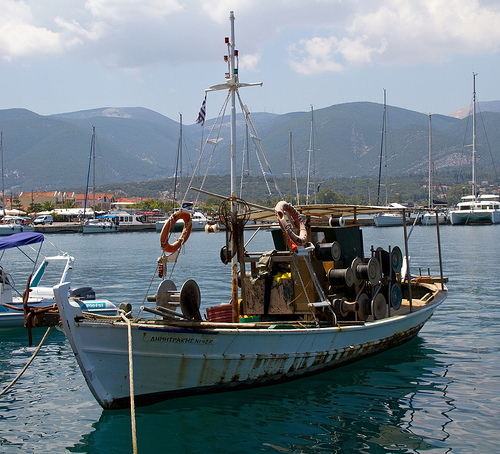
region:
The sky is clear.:
[267, 28, 444, 86]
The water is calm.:
[370, 376, 480, 438]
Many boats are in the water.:
[26, 83, 497, 427]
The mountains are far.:
[27, 82, 468, 193]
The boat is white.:
[52, 291, 442, 401]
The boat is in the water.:
[35, 189, 469, 427]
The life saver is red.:
[149, 208, 207, 259]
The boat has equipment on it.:
[95, 55, 433, 432]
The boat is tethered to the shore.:
[53, 12, 468, 424]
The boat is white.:
[445, 186, 499, 234]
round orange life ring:
[271, 191, 311, 253]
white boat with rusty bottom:
[52, 302, 449, 409]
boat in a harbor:
[59, 185, 454, 432]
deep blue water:
[327, 371, 478, 444]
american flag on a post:
[192, 82, 213, 169]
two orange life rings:
[152, 193, 317, 259]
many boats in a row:
[297, 97, 498, 227]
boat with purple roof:
[1, 227, 61, 342]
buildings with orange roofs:
[15, 185, 150, 218]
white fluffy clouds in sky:
[304, 9, 489, 64]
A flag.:
[174, 83, 224, 141]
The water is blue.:
[458, 232, 499, 380]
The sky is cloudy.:
[28, 7, 183, 94]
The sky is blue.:
[29, 12, 168, 95]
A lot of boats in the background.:
[1, 192, 151, 237]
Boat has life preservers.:
[137, 180, 317, 263]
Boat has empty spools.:
[315, 242, 416, 331]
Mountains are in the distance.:
[299, 81, 493, 186]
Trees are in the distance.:
[320, 160, 421, 196]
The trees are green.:
[313, 162, 381, 191]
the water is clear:
[337, 368, 423, 449]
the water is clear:
[313, 401, 386, 448]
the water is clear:
[342, 407, 387, 452]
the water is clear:
[300, 356, 385, 442]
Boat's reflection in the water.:
[70, 347, 452, 446]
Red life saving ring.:
[156, 210, 198, 250]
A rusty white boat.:
[57, 274, 452, 406]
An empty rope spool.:
[149, 276, 204, 315]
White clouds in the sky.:
[284, 2, 496, 77]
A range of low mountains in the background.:
[3, 97, 498, 196]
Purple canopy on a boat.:
[0, 231, 47, 248]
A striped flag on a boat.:
[195, 91, 210, 122]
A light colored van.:
[34, 213, 55, 224]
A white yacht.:
[448, 195, 498, 222]